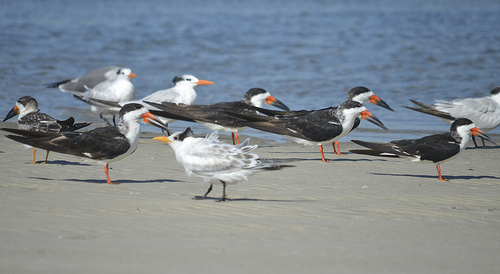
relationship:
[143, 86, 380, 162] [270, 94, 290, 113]
birds have beaks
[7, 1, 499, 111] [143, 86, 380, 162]
water behind birds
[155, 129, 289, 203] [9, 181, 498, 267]
bird on sand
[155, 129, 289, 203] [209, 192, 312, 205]
bird has shadow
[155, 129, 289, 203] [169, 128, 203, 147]
bird has head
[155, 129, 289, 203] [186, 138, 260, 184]
bird has feathers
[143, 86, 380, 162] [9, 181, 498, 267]
birds on sand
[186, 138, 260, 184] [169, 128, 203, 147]
feathers on head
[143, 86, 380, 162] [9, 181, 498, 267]
birds in sand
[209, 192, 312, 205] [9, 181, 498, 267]
shadow in sand